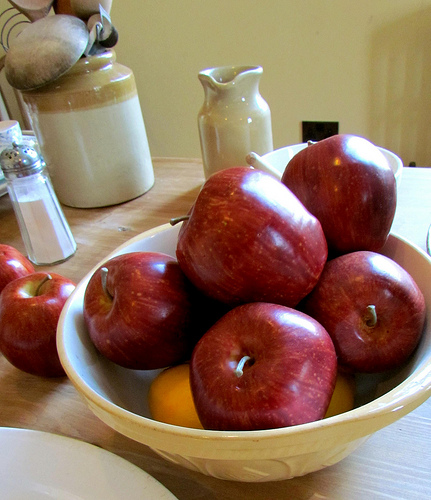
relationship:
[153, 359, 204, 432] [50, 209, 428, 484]
orange inside bowl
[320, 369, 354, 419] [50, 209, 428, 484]
orange inside bowl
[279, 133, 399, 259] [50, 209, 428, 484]
apple in bowl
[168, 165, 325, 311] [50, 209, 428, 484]
apple in bowl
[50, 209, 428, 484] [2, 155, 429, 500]
bowl on top of table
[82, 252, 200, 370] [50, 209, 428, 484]
apple in bowl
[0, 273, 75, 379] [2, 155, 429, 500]
apple on top of table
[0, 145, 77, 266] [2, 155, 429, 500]
salt shaker on table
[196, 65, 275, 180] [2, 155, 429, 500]
pitcher on table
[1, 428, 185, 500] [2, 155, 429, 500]
plate on top of table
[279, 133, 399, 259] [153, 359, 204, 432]
apple on top of orange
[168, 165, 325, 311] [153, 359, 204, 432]
apple on top of orange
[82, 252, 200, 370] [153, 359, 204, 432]
apple on top of orange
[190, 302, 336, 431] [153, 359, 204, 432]
apple on top of orange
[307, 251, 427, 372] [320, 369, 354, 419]
apple on top of orange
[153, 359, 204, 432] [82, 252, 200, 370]
orange under apple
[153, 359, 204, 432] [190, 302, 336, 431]
orange under apple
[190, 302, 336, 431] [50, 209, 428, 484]
apple in bowl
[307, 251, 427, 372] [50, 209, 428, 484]
apple in bowl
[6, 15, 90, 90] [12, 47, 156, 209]
ladle in jar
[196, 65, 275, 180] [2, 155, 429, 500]
pitcher on top of table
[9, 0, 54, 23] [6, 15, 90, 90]
spoon behind ladle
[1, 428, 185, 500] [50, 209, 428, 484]
plate in front of bowl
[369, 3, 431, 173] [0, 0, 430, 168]
shadow on wall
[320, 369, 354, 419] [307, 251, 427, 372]
orange under apple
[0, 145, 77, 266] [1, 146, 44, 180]
salt shaker has cap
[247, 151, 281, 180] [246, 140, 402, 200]
handle in bowl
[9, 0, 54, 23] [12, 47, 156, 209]
spoon in jar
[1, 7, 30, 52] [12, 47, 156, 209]
whisk in jar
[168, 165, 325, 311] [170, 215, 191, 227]
apple has stem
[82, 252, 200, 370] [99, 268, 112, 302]
apple has stem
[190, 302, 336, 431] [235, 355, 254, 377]
apple has stem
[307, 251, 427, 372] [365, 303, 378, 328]
apple has stem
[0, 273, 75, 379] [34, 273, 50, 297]
apple has stem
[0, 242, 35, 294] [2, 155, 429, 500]
apple on top of table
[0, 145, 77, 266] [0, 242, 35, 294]
salt shaker behind apple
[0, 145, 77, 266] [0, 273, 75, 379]
salt shaker behind apple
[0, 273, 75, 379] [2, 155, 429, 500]
apple on table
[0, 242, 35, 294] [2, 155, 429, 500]
apple on table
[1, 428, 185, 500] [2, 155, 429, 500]
plate on table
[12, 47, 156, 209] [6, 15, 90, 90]
jar has ladle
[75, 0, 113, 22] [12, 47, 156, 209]
spoon in jar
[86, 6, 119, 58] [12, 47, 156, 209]
utensil in jar